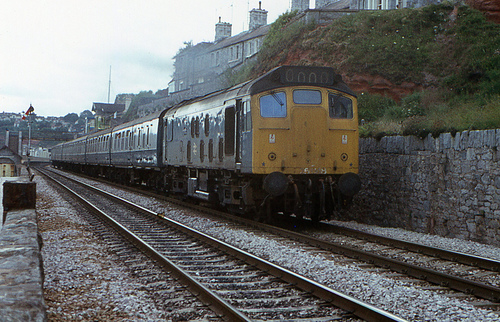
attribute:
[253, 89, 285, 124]
windshield — black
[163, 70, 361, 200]
train — yellow, long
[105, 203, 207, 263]
train tracks — black, long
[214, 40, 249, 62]
building — grey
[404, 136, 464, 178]
stone wall — grey